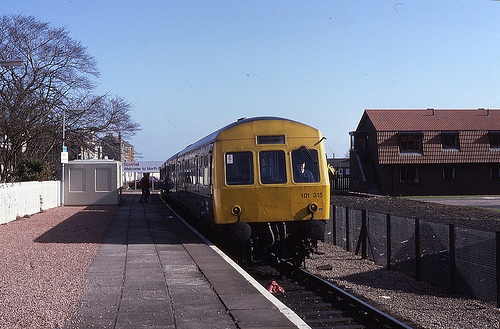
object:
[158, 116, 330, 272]
train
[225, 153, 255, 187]
window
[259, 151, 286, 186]
window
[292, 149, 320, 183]
window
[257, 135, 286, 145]
window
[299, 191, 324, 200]
number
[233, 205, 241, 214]
light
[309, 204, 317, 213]
light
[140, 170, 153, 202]
people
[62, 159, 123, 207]
building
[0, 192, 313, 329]
platform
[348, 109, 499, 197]
building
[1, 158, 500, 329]
train station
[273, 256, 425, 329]
track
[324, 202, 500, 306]
fence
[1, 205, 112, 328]
rocks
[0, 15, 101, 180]
trees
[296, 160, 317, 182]
engineer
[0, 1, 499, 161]
sky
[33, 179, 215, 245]
shadow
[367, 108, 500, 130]
roof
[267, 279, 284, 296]
object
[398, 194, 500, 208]
concrete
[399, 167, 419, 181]
window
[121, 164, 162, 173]
banner